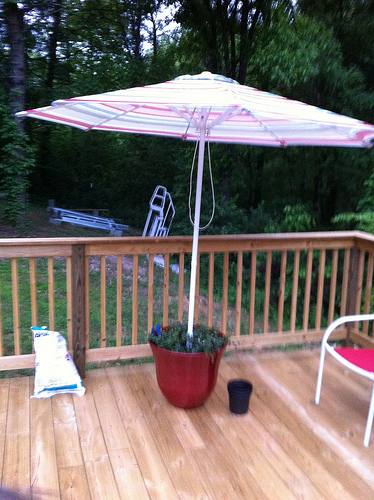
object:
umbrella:
[11, 67, 374, 150]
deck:
[72, 369, 121, 498]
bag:
[30, 322, 87, 401]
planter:
[149, 326, 229, 410]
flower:
[154, 322, 166, 334]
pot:
[227, 377, 251, 414]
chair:
[312, 312, 374, 449]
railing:
[0, 227, 373, 371]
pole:
[52, 205, 129, 232]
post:
[186, 131, 206, 338]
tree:
[229, 4, 373, 229]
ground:
[0, 203, 345, 373]